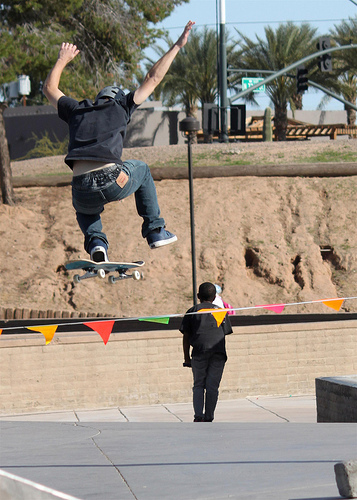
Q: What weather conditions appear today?
A: It is clear.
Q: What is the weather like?
A: It is clear.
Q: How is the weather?
A: It is clear.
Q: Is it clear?
A: Yes, it is clear.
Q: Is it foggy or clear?
A: It is clear.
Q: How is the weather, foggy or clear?
A: It is clear.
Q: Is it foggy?
A: No, it is clear.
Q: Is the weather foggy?
A: No, it is clear.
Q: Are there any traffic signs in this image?
A: Yes, there is a traffic sign.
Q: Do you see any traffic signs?
A: Yes, there is a traffic sign.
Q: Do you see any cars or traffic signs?
A: Yes, there is a traffic sign.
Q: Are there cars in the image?
A: No, there are no cars.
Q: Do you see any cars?
A: No, there are no cars.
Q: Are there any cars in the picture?
A: No, there are no cars.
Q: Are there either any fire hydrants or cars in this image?
A: No, there are no cars or fire hydrants.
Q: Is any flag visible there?
A: Yes, there is a flag.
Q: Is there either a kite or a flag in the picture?
A: Yes, there is a flag.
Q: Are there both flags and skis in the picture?
A: No, there is a flag but no skis.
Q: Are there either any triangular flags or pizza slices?
A: Yes, there is a triangular flag.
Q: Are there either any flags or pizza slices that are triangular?
A: Yes, the flag is triangular.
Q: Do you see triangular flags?
A: Yes, there is a triangular flag.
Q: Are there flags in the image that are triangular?
A: Yes, there is a flag that is triangular.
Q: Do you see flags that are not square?
A: Yes, there is a triangular flag.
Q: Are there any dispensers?
A: No, there are no dispensers.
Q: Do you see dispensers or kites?
A: No, there are no dispensers or kites.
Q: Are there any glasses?
A: No, there are no glasses.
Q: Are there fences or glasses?
A: No, there are no glasses or fences.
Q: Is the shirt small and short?
A: Yes, the shirt is small and short.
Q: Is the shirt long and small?
A: No, the shirt is small but short.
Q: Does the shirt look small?
A: Yes, the shirt is small.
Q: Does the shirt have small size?
A: Yes, the shirt is small.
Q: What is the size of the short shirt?
A: The shirt is small.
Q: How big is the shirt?
A: The shirt is small.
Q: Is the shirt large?
A: No, the shirt is small.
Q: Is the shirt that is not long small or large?
A: The shirt is small.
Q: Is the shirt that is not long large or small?
A: The shirt is small.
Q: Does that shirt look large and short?
A: No, the shirt is short but small.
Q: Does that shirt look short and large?
A: No, the shirt is short but small.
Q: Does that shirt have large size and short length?
A: No, the shirt is short but small.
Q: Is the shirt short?
A: Yes, the shirt is short.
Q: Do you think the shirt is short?
A: Yes, the shirt is short.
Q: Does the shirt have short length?
A: Yes, the shirt is short.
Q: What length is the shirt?
A: The shirt is short.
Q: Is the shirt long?
A: No, the shirt is short.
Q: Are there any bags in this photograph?
A: No, there are no bags.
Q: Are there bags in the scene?
A: No, there are no bags.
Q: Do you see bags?
A: No, there are no bags.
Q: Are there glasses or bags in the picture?
A: No, there are no bags or glasses.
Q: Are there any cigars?
A: No, there are no cigars.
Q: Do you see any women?
A: No, there are no women.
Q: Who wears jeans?
A: The boy wears jeans.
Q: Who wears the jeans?
A: The boy wears jeans.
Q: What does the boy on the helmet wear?
A: The boy wears jeans.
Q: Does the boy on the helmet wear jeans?
A: Yes, the boy wears jeans.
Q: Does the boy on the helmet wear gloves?
A: No, the boy wears jeans.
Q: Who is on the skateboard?
A: The boy is on the skateboard.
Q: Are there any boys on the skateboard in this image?
A: Yes, there is a boy on the skateboard.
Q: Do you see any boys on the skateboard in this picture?
A: Yes, there is a boy on the skateboard.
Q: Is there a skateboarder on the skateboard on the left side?
A: No, there is a boy on the skateboard.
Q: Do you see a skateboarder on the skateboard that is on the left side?
A: No, there is a boy on the skateboard.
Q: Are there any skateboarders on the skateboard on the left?
A: No, there is a boy on the skateboard.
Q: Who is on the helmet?
A: The boy is on the helmet.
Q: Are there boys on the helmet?
A: Yes, there is a boy on the helmet.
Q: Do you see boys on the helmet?
A: Yes, there is a boy on the helmet.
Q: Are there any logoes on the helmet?
A: No, there is a boy on the helmet.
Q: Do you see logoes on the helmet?
A: No, there is a boy on the helmet.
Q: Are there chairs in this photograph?
A: No, there are no chairs.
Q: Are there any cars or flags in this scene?
A: Yes, there is a flag.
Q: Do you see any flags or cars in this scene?
A: Yes, there is a flag.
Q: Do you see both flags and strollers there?
A: No, there is a flag but no strollers.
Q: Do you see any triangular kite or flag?
A: Yes, there is a triangular flag.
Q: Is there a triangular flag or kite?
A: Yes, there is a triangular flag.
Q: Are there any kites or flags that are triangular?
A: Yes, the flag is triangular.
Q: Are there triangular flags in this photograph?
A: Yes, there is a triangular flag.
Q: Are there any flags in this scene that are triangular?
A: Yes, there is a flag that is triangular.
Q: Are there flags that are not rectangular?
A: Yes, there is a triangular flag.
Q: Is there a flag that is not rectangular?
A: Yes, there is a triangular flag.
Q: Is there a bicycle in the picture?
A: No, there are no bicycles.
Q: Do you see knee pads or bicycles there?
A: No, there are no bicycles or knee pads.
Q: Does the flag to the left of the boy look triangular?
A: Yes, the flag is triangular.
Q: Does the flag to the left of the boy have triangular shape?
A: Yes, the flag is triangular.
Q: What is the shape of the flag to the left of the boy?
A: The flag is triangular.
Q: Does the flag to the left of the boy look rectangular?
A: No, the flag is triangular.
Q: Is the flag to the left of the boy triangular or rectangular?
A: The flag is triangular.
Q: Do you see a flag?
A: Yes, there is a flag.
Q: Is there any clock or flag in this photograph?
A: Yes, there is a flag.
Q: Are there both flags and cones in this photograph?
A: No, there is a flag but no cones.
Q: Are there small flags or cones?
A: Yes, there is a small flag.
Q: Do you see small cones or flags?
A: Yes, there is a small flag.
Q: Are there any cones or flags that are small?
A: Yes, the flag is small.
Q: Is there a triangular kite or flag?
A: Yes, there is a triangular flag.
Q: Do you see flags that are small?
A: Yes, there is a small flag.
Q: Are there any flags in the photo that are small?
A: Yes, there is a flag that is small.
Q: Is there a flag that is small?
A: Yes, there is a flag that is small.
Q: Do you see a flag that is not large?
A: Yes, there is a small flag.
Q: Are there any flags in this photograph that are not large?
A: Yes, there is a small flag.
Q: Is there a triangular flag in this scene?
A: Yes, there is a triangular flag.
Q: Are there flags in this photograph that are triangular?
A: Yes, there is a flag that is triangular.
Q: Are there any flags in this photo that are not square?
A: Yes, there is a triangular flag.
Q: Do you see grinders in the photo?
A: No, there are no grinders.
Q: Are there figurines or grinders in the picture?
A: No, there are no grinders or figurines.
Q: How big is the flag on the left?
A: The flag is small.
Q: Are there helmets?
A: Yes, there is a helmet.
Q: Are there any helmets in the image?
A: Yes, there is a helmet.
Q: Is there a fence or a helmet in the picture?
A: Yes, there is a helmet.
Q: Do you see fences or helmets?
A: Yes, there is a helmet.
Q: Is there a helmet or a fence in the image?
A: Yes, there is a helmet.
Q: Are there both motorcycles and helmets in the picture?
A: No, there is a helmet but no motorcycles.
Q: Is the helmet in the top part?
A: Yes, the helmet is in the top of the image.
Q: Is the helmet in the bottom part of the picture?
A: No, the helmet is in the top of the image.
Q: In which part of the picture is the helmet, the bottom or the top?
A: The helmet is in the top of the image.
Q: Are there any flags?
A: Yes, there is a flag.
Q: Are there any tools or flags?
A: Yes, there is a flag.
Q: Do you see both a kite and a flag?
A: No, there is a flag but no kites.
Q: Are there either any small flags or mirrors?
A: Yes, there is a small flag.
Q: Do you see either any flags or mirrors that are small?
A: Yes, the flag is small.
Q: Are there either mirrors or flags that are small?
A: Yes, the flag is small.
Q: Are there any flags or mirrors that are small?
A: Yes, the flag is small.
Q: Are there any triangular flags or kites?
A: Yes, there is a triangular flag.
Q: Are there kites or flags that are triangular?
A: Yes, the flag is triangular.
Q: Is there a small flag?
A: Yes, there is a small flag.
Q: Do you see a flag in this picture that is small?
A: Yes, there is a flag that is small.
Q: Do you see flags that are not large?
A: Yes, there is a small flag.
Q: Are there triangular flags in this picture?
A: Yes, there is a triangular flag.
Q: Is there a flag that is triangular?
A: Yes, there is a flag that is triangular.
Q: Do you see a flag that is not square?
A: Yes, there is a triangular flag.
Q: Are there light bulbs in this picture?
A: No, there are no light bulbs.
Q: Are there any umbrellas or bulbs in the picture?
A: No, there are no bulbs or umbrellas.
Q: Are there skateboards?
A: Yes, there is a skateboard.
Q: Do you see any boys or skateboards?
A: Yes, there is a skateboard.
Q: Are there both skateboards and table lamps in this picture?
A: No, there is a skateboard but no table lamps.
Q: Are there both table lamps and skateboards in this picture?
A: No, there is a skateboard but no table lamps.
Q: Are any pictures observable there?
A: No, there are no pictures.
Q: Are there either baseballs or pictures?
A: No, there are no pictures or baseballs.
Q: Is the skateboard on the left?
A: Yes, the skateboard is on the left of the image.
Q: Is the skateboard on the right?
A: No, the skateboard is on the left of the image.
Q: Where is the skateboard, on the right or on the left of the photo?
A: The skateboard is on the left of the image.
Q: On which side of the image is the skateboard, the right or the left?
A: The skateboard is on the left of the image.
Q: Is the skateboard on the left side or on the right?
A: The skateboard is on the left of the image.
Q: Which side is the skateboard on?
A: The skateboard is on the left of the image.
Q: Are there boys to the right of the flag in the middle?
A: Yes, there is a boy to the right of the flag.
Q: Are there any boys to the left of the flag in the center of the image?
A: No, the boy is to the right of the flag.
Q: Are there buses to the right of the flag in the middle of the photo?
A: No, there is a boy to the right of the flag.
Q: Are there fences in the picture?
A: No, there are no fences.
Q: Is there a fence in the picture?
A: No, there are no fences.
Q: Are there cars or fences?
A: No, there are no fences or cars.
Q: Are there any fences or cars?
A: No, there are no fences or cars.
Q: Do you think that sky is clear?
A: Yes, the sky is clear.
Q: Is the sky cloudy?
A: No, the sky is clear.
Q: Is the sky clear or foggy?
A: The sky is clear.